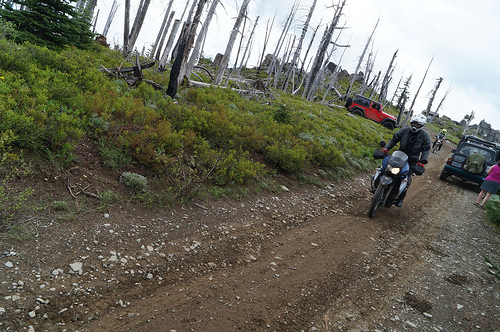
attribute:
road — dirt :
[0, 144, 498, 328]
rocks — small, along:
[2, 177, 499, 330]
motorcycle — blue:
[367, 142, 424, 217]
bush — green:
[5, 29, 78, 154]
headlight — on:
[385, 164, 400, 174]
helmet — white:
[411, 112, 427, 133]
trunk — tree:
[155, 19, 179, 71]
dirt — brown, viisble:
[34, 202, 419, 330]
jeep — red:
[344, 91, 399, 129]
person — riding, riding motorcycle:
[374, 113, 430, 207]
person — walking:
[475, 162, 500, 209]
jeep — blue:
[439, 135, 500, 188]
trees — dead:
[92, 3, 449, 136]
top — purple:
[484, 164, 498, 183]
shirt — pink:
[484, 163, 498, 180]